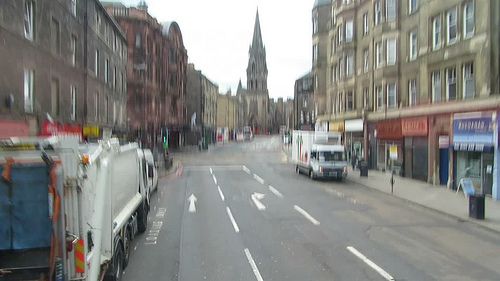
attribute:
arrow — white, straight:
[186, 191, 199, 213]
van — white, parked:
[292, 127, 346, 182]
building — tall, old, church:
[233, 7, 294, 133]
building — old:
[0, 2, 129, 144]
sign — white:
[344, 117, 364, 132]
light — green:
[160, 135, 169, 144]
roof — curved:
[158, 19, 186, 48]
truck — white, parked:
[1, 135, 150, 278]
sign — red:
[375, 117, 404, 141]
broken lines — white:
[242, 162, 395, 280]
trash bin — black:
[467, 191, 486, 219]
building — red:
[101, 2, 188, 151]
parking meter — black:
[389, 170, 396, 193]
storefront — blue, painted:
[453, 111, 497, 198]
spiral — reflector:
[72, 237, 86, 274]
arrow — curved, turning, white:
[251, 190, 268, 212]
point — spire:
[243, 7, 269, 71]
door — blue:
[437, 146, 450, 186]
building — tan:
[398, 4, 499, 200]